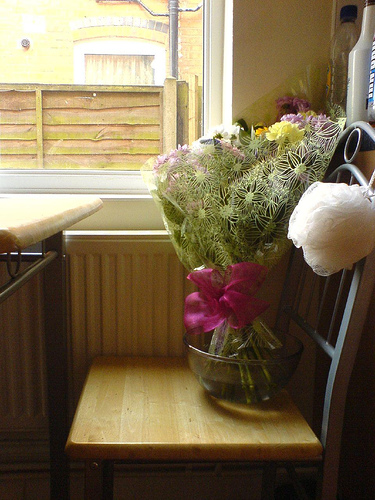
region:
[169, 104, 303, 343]
Flowers in wrapping paper.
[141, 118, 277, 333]
Red bow decorating flower bouquet.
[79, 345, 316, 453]
Shiny wooden chair seat.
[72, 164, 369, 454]
Wooden and metal chair.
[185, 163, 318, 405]
Flowers in a bowl full of water.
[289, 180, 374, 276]
Bath scrub hanging on a chair.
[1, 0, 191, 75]
Neighbor's window seen from the kitchen.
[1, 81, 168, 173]
Old blinds covering part of the window.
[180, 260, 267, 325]
Pink decorative bow.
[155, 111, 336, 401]
Variety of spring flowers.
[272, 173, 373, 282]
a whtie object near flowers.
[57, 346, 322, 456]
a wooden table top.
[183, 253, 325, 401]
a pink plant pot.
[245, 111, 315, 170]
a yellow flower.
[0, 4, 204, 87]
a window looking towards a building.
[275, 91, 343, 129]
purple flowers in a bundle.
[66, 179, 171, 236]
a white counter top.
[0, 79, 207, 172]
a wooden fence.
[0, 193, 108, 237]
a wooden table.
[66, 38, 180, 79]
a window on the side of a yellow building.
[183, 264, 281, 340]
a ribbon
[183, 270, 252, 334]
purple ribbon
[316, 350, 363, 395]
a chair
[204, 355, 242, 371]
a clear bowl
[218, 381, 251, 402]
water in the bowl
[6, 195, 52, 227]
a table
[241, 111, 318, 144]
yellow and purple flowers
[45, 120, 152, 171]
a window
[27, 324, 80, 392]
a pole connected to the table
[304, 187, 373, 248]
a white lofa on the chair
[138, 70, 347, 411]
Glass bowl contained a bouquet of flowers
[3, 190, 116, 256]
Brown wooden table top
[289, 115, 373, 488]
White shower poof hanging on silver chair back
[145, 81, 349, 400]
Bouquet of flowers with pink ribbon and green wrapping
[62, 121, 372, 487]
Chair with silver back and wood seat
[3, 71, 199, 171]
Outside wall made with rough wooden planks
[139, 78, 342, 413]
Bouquet of purple and yellow flowers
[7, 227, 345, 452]
White thin slatted wall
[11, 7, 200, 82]
Brick building with white windows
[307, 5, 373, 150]
Black shelf holding three bottles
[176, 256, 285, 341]
pink bow on bouquet of flowers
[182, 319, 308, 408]
glass water filled bowl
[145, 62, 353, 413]
bouquet of fowers in wrapped cellophane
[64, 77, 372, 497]
wooden chair with metal back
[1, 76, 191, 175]
wood slatted wall through window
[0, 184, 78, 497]
wooden table with metal legs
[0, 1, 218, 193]
window in wall in front of table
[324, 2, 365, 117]
clear bottle with black bottle cap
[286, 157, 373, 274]
white mesh shower sponge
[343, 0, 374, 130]
white plastic bottle with black bottle cap